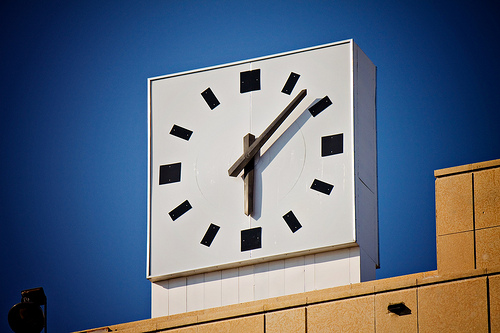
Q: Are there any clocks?
A: Yes, there is a clock.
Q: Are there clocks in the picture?
A: Yes, there is a clock.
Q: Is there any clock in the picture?
A: Yes, there is a clock.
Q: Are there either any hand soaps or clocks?
A: Yes, there is a clock.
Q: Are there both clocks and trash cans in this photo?
A: No, there is a clock but no trash cans.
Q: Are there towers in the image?
A: No, there are no towers.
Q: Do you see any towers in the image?
A: No, there are no towers.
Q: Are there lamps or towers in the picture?
A: No, there are no towers or lamps.